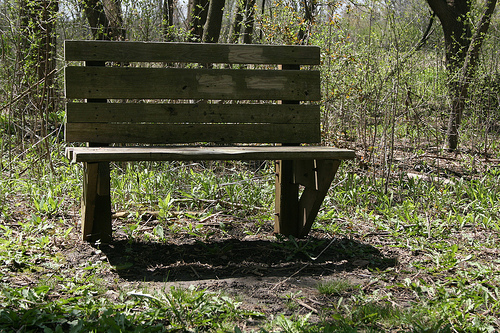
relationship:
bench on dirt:
[46, 23, 356, 245] [19, 200, 445, 312]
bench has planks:
[46, 23, 356, 245] [51, 37, 331, 141]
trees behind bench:
[4, 8, 467, 152] [46, 36, 350, 256]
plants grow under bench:
[1, 143, 496, 331] [46, 23, 356, 245]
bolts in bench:
[270, 162, 282, 234] [46, 23, 356, 245]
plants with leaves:
[335, 45, 422, 161] [314, 20, 425, 90]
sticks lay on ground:
[251, 210, 482, 279] [11, 194, 446, 322]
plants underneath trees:
[1, 143, 496, 331] [401, 10, 475, 147]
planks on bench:
[57, 40, 322, 144] [46, 23, 356, 245]